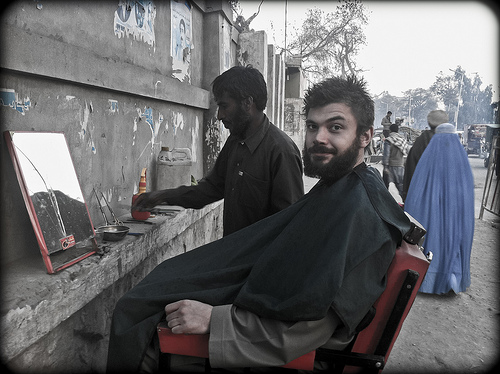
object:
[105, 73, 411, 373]
man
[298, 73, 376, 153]
hair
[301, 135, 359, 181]
beard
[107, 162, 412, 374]
cape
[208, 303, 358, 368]
shirt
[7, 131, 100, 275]
mirror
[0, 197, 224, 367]
shelf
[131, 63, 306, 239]
man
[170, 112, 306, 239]
shirt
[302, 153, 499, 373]
street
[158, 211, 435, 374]
chair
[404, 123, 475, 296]
woman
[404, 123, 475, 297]
headscarf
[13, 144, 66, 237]
crack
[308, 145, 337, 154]
mustache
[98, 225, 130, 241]
wash bowl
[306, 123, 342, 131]
eyes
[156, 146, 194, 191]
storage jug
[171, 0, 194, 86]
advertisement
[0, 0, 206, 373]
wall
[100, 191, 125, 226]
scissors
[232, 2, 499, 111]
sky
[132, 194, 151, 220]
cup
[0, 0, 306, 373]
building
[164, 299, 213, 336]
hand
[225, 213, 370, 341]
arm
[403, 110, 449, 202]
man